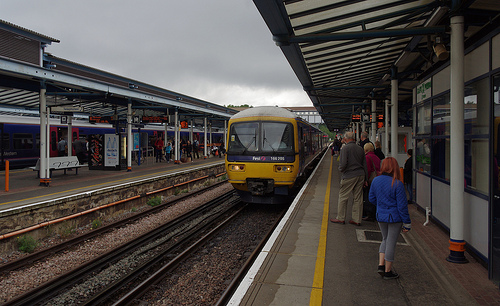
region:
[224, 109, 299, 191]
front of yellow train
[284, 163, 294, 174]
lights on the yellow train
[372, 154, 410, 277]
woman in blue coat waiting on train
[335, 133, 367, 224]
man in grey sweater waiting on train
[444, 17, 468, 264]
white support pole for building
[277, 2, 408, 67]
metal and plastic awning over people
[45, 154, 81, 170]
white and wood bench under awning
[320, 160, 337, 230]
yellow caution line beside tracks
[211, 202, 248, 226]
black metal train tracks beside train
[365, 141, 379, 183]
woman in red jacket waiting on train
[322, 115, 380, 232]
people standing at the platform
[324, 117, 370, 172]
people standing at the platform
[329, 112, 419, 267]
people standing at the platform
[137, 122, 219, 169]
people standing at the platform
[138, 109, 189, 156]
people standing at the platform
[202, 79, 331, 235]
the train is yellow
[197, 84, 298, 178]
the train is yellow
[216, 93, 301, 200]
yellow passenger train in station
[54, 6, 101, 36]
white clouds in blue sky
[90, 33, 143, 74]
white clouds in blue sky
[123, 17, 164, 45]
white clouds in blue sky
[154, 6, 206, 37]
white clouds in blue sky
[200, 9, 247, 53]
white clouds in blue sky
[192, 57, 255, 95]
white clouds in blue sky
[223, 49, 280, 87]
white clouds in blue sky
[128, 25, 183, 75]
white clouds in blue sky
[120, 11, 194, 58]
white clouds in blue sky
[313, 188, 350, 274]
a yellow painted line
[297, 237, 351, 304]
a yellow painted line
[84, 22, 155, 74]
the sky is gray and cloudy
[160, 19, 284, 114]
the sky is gray and cloudy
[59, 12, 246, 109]
the sky is gray and cloudy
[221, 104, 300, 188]
yellow train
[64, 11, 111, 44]
white clouds in blue sky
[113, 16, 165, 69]
white clouds in blue sky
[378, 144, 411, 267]
person waiting for train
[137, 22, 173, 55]
white clouds in blue sky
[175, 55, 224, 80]
white clouds in blue sky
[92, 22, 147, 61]
white clouds in blue sky